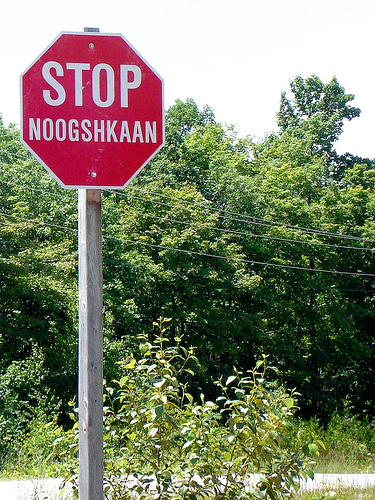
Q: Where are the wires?
A: Behind the stop sign.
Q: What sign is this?
A: A stop sign.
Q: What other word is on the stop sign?
A: NOOGISHKAAN.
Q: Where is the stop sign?
A: On a wooden pole.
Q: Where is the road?
A: Behind the stop sign.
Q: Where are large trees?
A: Behind the road.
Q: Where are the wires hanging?
A: Over the road.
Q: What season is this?
A: Summer.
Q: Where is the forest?
A: Behind the stop sign.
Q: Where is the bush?
A: Next to sign.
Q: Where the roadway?
A: Along forest.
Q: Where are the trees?
A: In forest.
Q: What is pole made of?
A: Wood.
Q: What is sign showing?
A: English.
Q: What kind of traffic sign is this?
A: Stop sign.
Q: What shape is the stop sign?
A: Octagon.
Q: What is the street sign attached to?
A: Metal pole.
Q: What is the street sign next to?
A: Street.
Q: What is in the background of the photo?
A: Trees.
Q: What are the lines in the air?
A: Power lines.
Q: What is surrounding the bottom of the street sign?
A: Tall plants.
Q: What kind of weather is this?
A: Sunny with no clouds.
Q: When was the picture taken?
A: Daytime.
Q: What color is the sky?
A: White.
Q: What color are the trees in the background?
A: Green.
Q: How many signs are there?
A: One.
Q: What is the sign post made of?
A: Wood.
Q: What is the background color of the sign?
A: Red.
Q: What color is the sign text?
A: White.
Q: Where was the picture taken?
A: In a rural area.